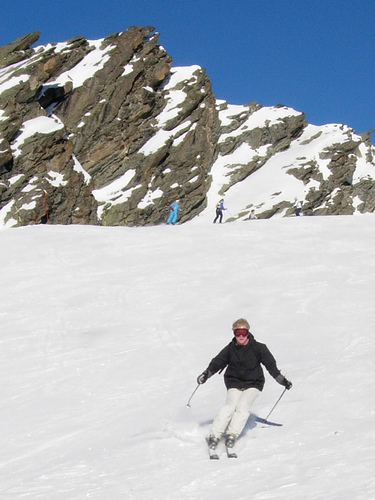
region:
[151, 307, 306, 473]
person skiing down a slope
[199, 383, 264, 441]
pair of white pants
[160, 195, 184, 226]
person skiing down a slope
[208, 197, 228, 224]
person skiing down a slope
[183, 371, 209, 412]
long silver ski pole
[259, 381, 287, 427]
long silver ski pole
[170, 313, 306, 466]
person wearing black jacket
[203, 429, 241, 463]
pair of silver skis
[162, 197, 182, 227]
person in blue ski suit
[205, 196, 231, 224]
person wearing black pants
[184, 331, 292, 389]
A black winter coat.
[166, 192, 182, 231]
A person dressed in all light blue.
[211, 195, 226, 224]
A person who is wearing purple.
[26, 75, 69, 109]
The shadow in the shape of a rectangle on the mountain.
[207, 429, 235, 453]
A pair of silver ski boots.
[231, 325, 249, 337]
A pair of ski goggles.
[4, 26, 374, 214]
A large area of rocky edge.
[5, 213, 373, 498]
A large area of snow being sued for skiing.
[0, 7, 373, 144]
A large area of open blue sky.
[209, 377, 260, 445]
A pair of white pant.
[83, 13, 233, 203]
the landscape is hilly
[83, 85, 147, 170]
the hill is brown in colour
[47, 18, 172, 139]
the mountain is covered with snow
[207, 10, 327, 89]
the sky is blue in colour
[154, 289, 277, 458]
the man is skiing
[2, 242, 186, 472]
the snow is white in colour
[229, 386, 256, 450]
the pants are white in colour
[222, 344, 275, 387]
the jacket is black in colour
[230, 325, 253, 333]
the goggles are red in colour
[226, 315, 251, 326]
the hat is silver in colour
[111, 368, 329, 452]
this is a skier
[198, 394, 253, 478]
the pants are white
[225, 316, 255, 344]
these are googles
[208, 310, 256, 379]
the goggles are red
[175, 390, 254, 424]
these are white snowpants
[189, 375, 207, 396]
this is a pole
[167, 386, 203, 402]
the pole is metal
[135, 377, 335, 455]
there are two poles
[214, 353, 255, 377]
this is a jacket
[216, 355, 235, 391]
the jacket is navy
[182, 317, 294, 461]
person wearing ski goggles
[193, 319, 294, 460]
skier wearing white pants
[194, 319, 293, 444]
ski holding ski poles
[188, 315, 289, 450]
person standing on skis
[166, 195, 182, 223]
skier behind skier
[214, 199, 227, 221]
skier in front of skier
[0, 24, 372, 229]
gray rock behind skier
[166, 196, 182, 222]
person wearing light blue ski suit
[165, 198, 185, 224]
person walking on snow